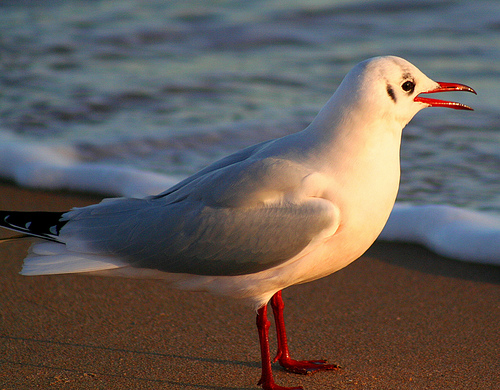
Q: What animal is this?
A: A bird.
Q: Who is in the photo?
A: No one.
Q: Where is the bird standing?
A: On the san.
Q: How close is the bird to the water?
A: A foot.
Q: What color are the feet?
A: Orange.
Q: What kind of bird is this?
A: Seabird.